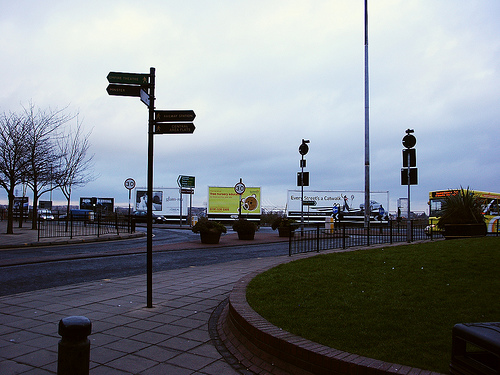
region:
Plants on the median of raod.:
[189, 203, 314, 245]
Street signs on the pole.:
[104, 70, 162, 100]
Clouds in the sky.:
[48, 16, 420, 135]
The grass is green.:
[316, 241, 470, 318]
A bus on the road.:
[418, 168, 495, 234]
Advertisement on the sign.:
[196, 175, 274, 230]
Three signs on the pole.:
[291, 135, 309, 232]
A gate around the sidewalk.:
[33, 206, 143, 246]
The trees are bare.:
[10, 108, 74, 227]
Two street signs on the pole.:
[158, 100, 215, 136]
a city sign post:
[101, 56, 193, 329]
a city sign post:
[291, 136, 317, 238]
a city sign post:
[396, 123, 426, 243]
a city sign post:
[172, 166, 199, 223]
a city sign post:
[118, 167, 142, 234]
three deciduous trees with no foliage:
[0, 101, 82, 243]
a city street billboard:
[281, 184, 392, 231]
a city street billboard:
[205, 183, 265, 215]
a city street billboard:
[126, 185, 194, 219]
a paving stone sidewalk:
[12, 273, 212, 370]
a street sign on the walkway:
[106, 67, 198, 311]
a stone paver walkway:
[91, 305, 214, 374]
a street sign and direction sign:
[401, 126, 419, 216]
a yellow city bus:
[426, 188, 498, 237]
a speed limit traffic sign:
[123, 175, 137, 214]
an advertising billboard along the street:
[205, 185, 262, 215]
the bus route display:
[432, 190, 459, 197]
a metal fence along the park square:
[287, 218, 434, 254]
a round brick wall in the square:
[227, 237, 464, 374]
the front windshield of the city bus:
[428, 197, 442, 214]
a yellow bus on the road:
[425, 174, 497, 241]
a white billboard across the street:
[326, 188, 341, 208]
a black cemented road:
[83, 250, 135, 270]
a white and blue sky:
[257, 142, 267, 159]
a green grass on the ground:
[345, 275, 375, 316]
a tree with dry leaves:
[23, 147, 61, 187]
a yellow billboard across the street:
[216, 188, 230, 211]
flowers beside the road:
[191, 218, 296, 243]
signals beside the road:
[389, 125, 421, 216]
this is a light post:
[89, 57, 193, 309]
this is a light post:
[291, 133, 337, 265]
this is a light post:
[393, 112, 430, 239]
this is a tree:
[39, 123, 101, 225]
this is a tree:
[17, 123, 60, 245]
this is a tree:
[1, 106, 47, 260]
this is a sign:
[224, 174, 249, 199]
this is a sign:
[176, 169, 200, 199]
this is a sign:
[109, 175, 144, 200]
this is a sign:
[390, 131, 435, 191]